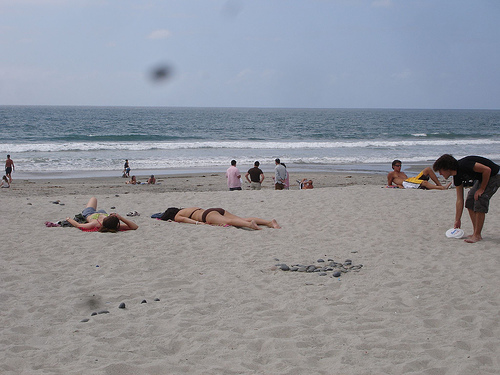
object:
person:
[242, 159, 267, 192]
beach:
[4, 243, 499, 374]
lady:
[155, 204, 282, 233]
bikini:
[187, 206, 229, 226]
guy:
[425, 151, 500, 245]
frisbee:
[444, 226, 467, 241]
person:
[40, 193, 140, 236]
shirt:
[452, 154, 499, 187]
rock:
[332, 269, 344, 281]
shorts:
[401, 168, 429, 193]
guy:
[385, 159, 453, 192]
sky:
[1, 0, 499, 108]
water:
[0, 107, 499, 179]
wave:
[4, 155, 500, 171]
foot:
[463, 235, 484, 244]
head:
[159, 206, 180, 222]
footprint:
[422, 315, 441, 332]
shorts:
[81, 206, 107, 220]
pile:
[265, 254, 365, 280]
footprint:
[480, 326, 500, 340]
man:
[0, 153, 18, 184]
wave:
[0, 132, 499, 155]